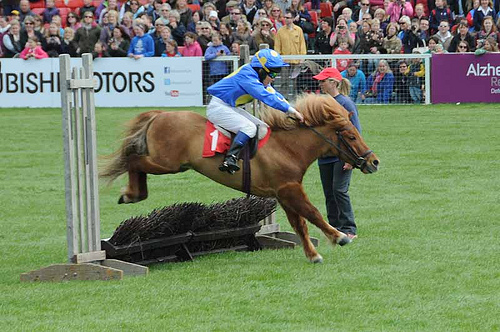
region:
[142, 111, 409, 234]
the horse is brown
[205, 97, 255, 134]
the pants are white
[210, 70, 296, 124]
the tshisrt is blue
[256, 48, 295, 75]
the helmet is blue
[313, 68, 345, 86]
the hat is red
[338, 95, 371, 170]
the tshisrt is blue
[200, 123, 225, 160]
the saddle is red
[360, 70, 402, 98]
the tshirt is blue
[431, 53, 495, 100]
the surface is purple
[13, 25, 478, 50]
the people are spectating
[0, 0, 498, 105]
the people in the audience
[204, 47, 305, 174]
the rider on the horse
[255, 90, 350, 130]
the mane on the horse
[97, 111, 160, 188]
the tail on the horse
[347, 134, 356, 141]
the eye on the horse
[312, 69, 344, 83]
the hat on the woman's head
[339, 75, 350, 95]
the ponytail on the woman standing near the horse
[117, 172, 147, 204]
the horse's back legs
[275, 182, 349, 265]
the horse's front legs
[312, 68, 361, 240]
the woman standing near the horse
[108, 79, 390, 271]
a pony is jumping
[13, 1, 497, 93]
a crowd of people watch the event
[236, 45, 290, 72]
the rider is wearing a helmet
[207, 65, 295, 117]
the riders jacket is blue and yellow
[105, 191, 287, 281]
the item the pony is jumping over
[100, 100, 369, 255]
the pony is brown in color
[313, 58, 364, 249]
a woman stands nearby as the pony jumps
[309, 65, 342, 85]
the woman is wearing an orange hat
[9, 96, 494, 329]
the ground is covered in grass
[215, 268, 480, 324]
the grass is green in color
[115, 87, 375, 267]
light horse jumping over fence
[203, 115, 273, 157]
red and white saddle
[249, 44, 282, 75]
blue and yellow helmet on head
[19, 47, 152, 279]
wooden gate around jump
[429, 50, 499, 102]
purple and white sign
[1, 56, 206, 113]
white sign with black lettering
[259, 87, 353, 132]
light brown mane flowing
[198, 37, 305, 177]
horse jockey wearing blue and white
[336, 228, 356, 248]
hoof of jumping horse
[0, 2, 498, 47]
spectators in stands watching event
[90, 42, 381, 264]
man wearing blue riding horse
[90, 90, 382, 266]
horse have number 1 on saddle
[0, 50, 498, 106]
advertising logo on fence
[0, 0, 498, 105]
people standing behind fence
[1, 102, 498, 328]
horse jumping on green grass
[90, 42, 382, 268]
man wearing white pants ridding horse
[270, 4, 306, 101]
man in yellow shirt wearing glasses standing up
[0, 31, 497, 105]
little girl wearing pink braising on fence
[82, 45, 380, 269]
man riding brown horse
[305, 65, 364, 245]
woman wearing red hat